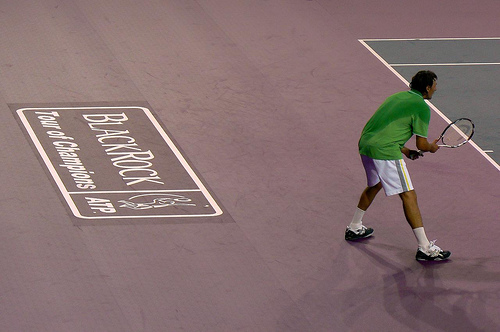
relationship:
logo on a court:
[12, 101, 224, 232] [2, 2, 496, 327]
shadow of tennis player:
[355, 241, 499, 331] [346, 67, 451, 262]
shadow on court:
[355, 241, 499, 331] [2, 2, 496, 327]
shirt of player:
[352, 90, 432, 162] [339, 60, 479, 265]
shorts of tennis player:
[359, 152, 414, 195] [346, 67, 451, 262]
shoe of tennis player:
[414, 244, 452, 261] [346, 67, 451, 262]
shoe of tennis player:
[344, 225, 375, 238] [346, 67, 451, 262]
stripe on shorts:
[393, 162, 411, 193] [361, 154, 414, 194]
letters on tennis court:
[33, 109, 166, 217] [1, 1, 498, 330]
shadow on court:
[371, 240, 481, 310] [2, 2, 496, 327]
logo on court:
[12, 105, 223, 218] [2, 2, 496, 327]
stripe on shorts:
[394, 159, 411, 192] [352, 148, 409, 200]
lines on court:
[358, 37, 498, 169] [2, 2, 496, 327]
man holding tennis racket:
[326, 55, 483, 277] [417, 105, 484, 160]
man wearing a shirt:
[342, 66, 452, 267] [354, 81, 435, 164]